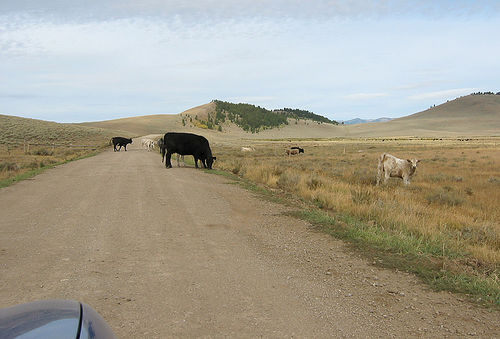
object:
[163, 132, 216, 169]
cow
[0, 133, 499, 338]
road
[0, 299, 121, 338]
vehicle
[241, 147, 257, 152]
cow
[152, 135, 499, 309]
field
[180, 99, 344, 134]
forest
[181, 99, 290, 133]
hill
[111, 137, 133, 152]
cow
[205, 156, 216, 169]
head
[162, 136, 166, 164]
tail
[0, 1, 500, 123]
sky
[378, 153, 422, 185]
cow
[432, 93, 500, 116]
hill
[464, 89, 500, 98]
forest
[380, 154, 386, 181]
tail